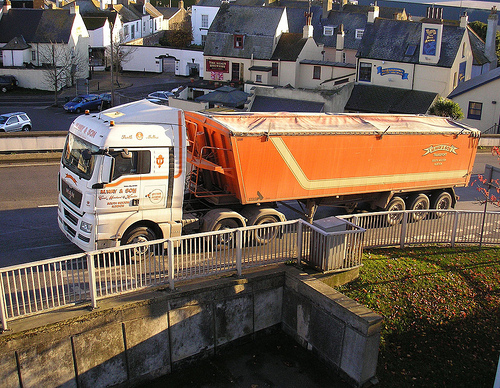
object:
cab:
[54, 99, 187, 263]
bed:
[213, 112, 471, 189]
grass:
[330, 245, 499, 388]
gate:
[73, 248, 206, 286]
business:
[363, 40, 454, 125]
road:
[0, 75, 500, 319]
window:
[312, 68, 321, 77]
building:
[208, 29, 340, 100]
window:
[233, 66, 241, 71]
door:
[231, 62, 239, 88]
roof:
[244, 8, 282, 59]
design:
[145, 148, 173, 171]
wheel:
[434, 191, 455, 219]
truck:
[59, 96, 498, 267]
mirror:
[79, 145, 116, 162]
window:
[63, 136, 97, 175]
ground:
[405, 259, 494, 323]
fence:
[0, 208, 500, 329]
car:
[63, 91, 105, 116]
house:
[447, 68, 499, 136]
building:
[186, 7, 212, 41]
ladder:
[185, 124, 208, 201]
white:
[135, 114, 166, 122]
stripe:
[102, 174, 162, 183]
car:
[144, 88, 174, 101]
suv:
[0, 112, 32, 131]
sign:
[420, 20, 438, 67]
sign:
[203, 58, 232, 73]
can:
[309, 216, 352, 270]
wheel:
[408, 195, 426, 223]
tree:
[474, 174, 494, 246]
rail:
[83, 236, 166, 256]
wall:
[0, 267, 375, 388]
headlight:
[79, 219, 93, 233]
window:
[123, 22, 134, 40]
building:
[115, 1, 144, 42]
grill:
[62, 202, 95, 225]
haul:
[241, 124, 416, 126]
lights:
[82, 110, 118, 136]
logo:
[417, 138, 462, 160]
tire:
[381, 201, 410, 220]